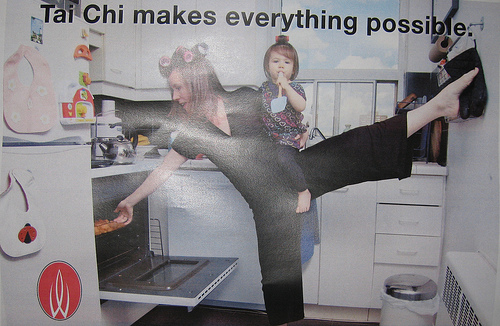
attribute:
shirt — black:
[186, 114, 294, 188]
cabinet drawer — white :
[370, 169, 447, 209]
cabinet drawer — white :
[373, 197, 443, 237]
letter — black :
[36, 2, 56, 21]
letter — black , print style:
[50, 8, 66, 19]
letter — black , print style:
[64, 2, 77, 22]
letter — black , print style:
[77, 2, 102, 27]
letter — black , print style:
[98, 0, 116, 29]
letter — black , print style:
[128, 3, 159, 30]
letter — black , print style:
[155, 5, 171, 29]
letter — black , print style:
[172, 6, 187, 26]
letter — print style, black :
[183, 5, 212, 44]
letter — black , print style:
[204, 6, 217, 30]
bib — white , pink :
[8, 40, 65, 135]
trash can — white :
[376, 267, 436, 324]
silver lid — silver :
[374, 267, 458, 308]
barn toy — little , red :
[57, 82, 99, 122]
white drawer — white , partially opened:
[371, 196, 449, 240]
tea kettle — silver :
[101, 130, 135, 162]